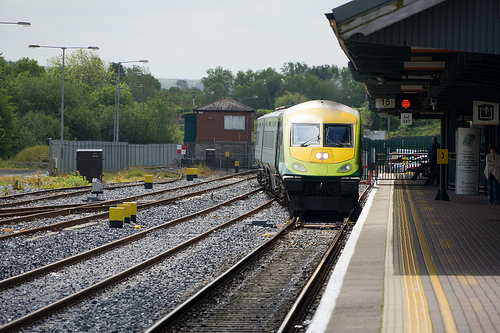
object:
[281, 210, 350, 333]
ties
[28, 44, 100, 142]
lights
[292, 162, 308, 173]
headlight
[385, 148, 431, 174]
cars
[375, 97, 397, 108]
sign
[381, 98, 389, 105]
black number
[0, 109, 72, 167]
tree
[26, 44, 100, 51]
streetlights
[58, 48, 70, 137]
pole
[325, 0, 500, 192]
station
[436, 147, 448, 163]
sign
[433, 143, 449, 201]
post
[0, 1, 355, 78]
sky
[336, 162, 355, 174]
headlight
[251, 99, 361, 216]
train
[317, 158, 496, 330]
platform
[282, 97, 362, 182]
front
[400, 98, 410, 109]
light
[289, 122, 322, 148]
window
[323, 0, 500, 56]
roof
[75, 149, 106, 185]
electrical box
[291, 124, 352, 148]
windshield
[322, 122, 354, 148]
window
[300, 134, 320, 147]
wiper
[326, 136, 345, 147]
wiper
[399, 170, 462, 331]
line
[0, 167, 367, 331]
rail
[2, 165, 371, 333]
ground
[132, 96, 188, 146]
tree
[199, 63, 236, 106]
tree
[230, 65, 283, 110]
tree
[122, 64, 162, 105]
tree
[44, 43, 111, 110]
tree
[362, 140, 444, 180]
fence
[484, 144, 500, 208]
woman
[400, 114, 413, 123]
signs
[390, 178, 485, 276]
shade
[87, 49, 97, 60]
leaves